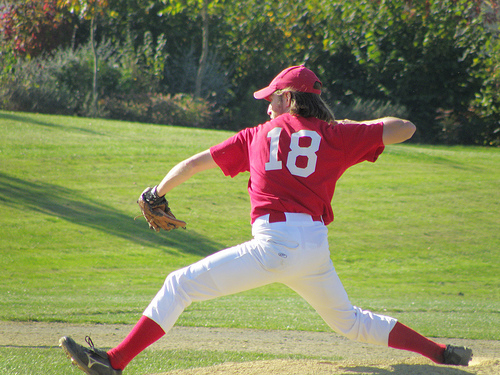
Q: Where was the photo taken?
A: It was taken at the lawn.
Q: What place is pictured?
A: It is a lawn.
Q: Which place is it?
A: It is a lawn.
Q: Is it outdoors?
A: Yes, it is outdoors.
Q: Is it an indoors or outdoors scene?
A: It is outdoors.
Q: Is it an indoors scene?
A: No, it is outdoors.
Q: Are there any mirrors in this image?
A: No, there are no mirrors.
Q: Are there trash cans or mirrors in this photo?
A: No, there are no mirrors or trash cans.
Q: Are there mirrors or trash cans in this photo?
A: No, there are no mirrors or trash cans.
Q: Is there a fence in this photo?
A: No, there are no fences.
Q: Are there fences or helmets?
A: No, there are no fences or helmets.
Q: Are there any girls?
A: No, there are no girls.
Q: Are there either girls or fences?
A: No, there are no girls or fences.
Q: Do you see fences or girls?
A: No, there are no girls or fences.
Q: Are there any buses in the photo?
A: No, there are no buses.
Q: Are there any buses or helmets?
A: No, there are no buses or helmets.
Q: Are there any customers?
A: No, there are no customers.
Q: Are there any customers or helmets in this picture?
A: No, there are no customers or helmets.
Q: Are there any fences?
A: No, there are no fences.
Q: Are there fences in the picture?
A: No, there are no fences.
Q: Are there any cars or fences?
A: No, there are no fences or cars.